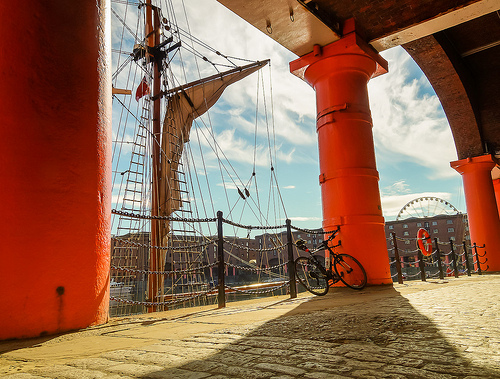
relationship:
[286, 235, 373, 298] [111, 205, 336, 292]
bike leaning against fence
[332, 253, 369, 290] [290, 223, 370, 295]
tire on bike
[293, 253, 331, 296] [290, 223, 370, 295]
tire on bike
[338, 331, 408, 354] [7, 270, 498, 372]
brick on walk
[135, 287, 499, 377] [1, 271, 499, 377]
shadow on ground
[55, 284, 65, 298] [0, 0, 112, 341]
spot on pillar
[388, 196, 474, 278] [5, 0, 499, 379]
ferris wheel behind building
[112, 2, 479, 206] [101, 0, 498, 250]
cloud in sky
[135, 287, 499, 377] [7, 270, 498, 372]
shadow on walk